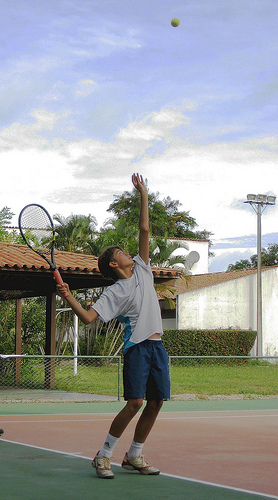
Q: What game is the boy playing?
A: Tennis.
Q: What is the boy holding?
A: Tennis racket.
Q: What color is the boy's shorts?
A: Blue.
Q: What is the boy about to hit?
A: Ball.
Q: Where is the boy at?
A: Tennis court.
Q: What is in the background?
A: Fence.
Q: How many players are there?
A: One.